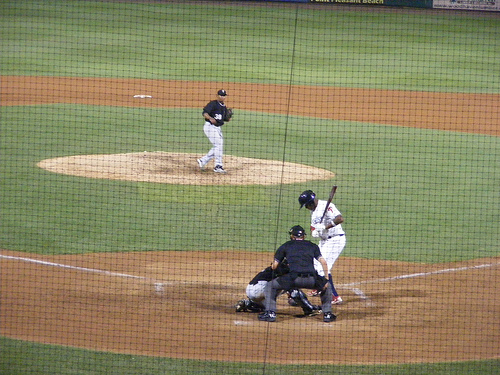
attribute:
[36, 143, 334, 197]
mound — brown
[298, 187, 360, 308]
player — standing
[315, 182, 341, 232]
bat — black, brown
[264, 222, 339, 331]
umpire — crouching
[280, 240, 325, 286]
protection — black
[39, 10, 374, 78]
astroturf — green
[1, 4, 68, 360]
netting — black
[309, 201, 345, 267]
uniform — white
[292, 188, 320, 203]
helmet — black, blue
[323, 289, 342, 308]
shoes — red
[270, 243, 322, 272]
shirt — black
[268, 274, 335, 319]
pants — grey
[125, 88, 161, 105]
base — second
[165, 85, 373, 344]
players — four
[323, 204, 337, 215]
stripe — red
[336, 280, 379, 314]
line — white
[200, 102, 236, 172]
uniform — black